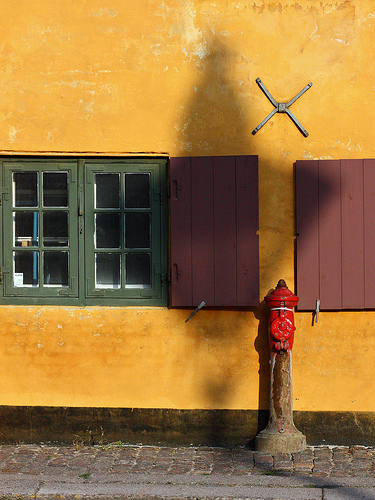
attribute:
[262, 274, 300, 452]
hydrant — fire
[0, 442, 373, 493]
pavement — bricked, stoned